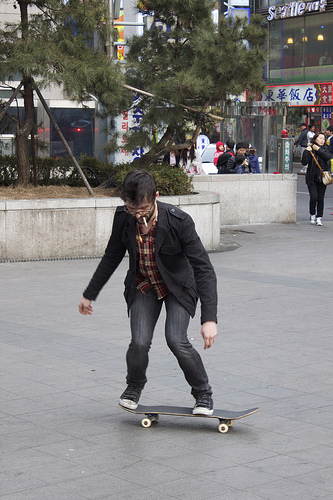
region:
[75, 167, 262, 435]
Man is on a skateboard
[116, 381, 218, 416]
Man is wearing shoes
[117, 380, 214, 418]
Man is wearing white and black shoes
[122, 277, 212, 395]
Man is wearing jeans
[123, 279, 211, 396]
Man is wearing dark jeans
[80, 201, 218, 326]
Man is wearing a coat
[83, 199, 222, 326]
Man is wearing a black coat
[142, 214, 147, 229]
Man has cigarette in his mouth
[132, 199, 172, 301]
Man is wearing a shirt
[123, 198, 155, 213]
Man is wearing glasses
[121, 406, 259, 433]
black skateboard being rode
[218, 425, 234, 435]
white wheel on skateboard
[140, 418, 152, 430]
white wheel on skateboard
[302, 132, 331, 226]
asian women wearing purse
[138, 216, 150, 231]
cigarette hanging from man's mouth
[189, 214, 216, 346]
skateboarding man's left arm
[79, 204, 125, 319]
skateboarding man's right arm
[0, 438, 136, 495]
cement pavemen on ground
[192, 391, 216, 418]
skateboarder's black left shoe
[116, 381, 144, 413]
skateboarder's black right shoe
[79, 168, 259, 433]
a man on skateboard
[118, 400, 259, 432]
a black and white skateboard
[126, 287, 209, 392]
a pair of black jeans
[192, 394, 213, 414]
a black and white shoe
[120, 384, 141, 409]
a black and white shoe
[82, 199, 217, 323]
a men's black coat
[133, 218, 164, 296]
a red plaid shirt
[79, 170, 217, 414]
a man smoking a cigarette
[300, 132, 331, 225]
a woman walking on sidewalk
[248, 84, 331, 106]
a business promotional sign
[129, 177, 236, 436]
the man is riding the skateboard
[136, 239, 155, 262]
the shirt is plaid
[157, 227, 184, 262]
the jacket is black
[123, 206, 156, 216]
the man is wearing glasses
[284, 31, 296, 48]
the light is on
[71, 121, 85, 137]
the light is red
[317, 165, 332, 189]
the bag is brown and white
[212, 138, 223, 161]
the coat is pink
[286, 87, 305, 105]
the word is blue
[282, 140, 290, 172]
the sign is green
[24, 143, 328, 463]
a man on a skateboard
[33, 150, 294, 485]
a man standing on a skateboard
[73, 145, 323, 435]
a man on the sidewalk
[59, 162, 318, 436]
a man riding a skateboard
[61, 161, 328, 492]
a man riding a skateboard on the sidewalk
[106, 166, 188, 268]
a man wearing glasses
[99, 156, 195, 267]
a man smoking a cigerate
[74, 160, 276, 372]
a man wearing a jacket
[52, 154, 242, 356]
a man wearing a black jacket